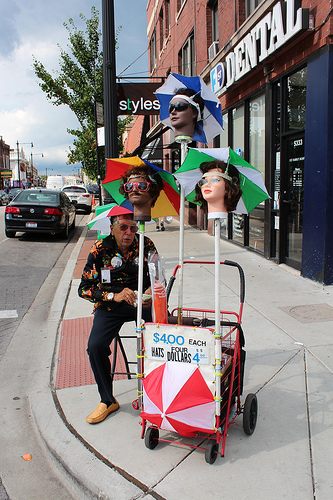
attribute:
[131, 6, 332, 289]
building — one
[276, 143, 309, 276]
window — one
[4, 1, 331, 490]
scene — outdoors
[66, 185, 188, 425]
man — sitting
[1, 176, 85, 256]
car — parked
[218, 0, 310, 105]
sign — a dental sign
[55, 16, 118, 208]
tree — tall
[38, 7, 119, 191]
leaves — green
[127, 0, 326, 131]
bricks — red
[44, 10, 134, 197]
leaves — green